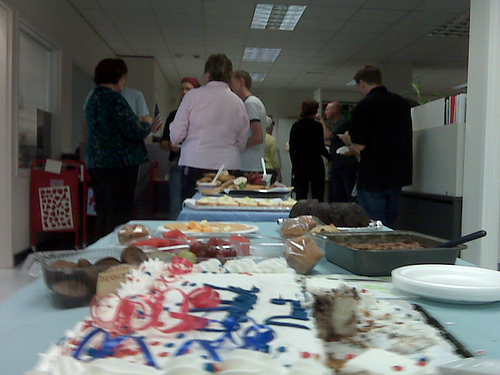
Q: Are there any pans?
A: Yes, there is a pan.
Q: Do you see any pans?
A: Yes, there is a pan.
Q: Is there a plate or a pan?
A: Yes, there is a pan.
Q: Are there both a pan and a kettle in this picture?
A: No, there is a pan but no kettles.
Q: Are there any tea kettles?
A: No, there are no tea kettles.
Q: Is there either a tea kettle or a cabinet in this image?
A: No, there are no tea kettles or cabinets.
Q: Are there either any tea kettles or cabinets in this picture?
A: No, there are no tea kettles or cabinets.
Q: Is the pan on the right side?
A: Yes, the pan is on the right of the image.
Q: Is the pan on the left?
A: No, the pan is on the right of the image.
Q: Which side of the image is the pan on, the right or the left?
A: The pan is on the right of the image.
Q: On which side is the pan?
A: The pan is on the right of the image.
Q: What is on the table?
A: The pan is on the table.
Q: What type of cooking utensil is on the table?
A: The cooking utensil is a pan.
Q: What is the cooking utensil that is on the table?
A: The cooking utensil is a pan.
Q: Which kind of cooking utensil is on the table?
A: The cooking utensil is a pan.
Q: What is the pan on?
A: The pan is on the table.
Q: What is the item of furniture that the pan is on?
A: The piece of furniture is a table.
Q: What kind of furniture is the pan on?
A: The pan is on the table.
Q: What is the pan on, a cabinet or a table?
A: The pan is on a table.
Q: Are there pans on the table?
A: Yes, there is a pan on the table.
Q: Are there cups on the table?
A: No, there is a pan on the table.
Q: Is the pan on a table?
A: Yes, the pan is on a table.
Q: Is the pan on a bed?
A: No, the pan is on a table.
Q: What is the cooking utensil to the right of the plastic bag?
A: The cooking utensil is a pan.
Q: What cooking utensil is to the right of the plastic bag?
A: The cooking utensil is a pan.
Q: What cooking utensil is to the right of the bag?
A: The cooking utensil is a pan.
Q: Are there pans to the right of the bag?
A: Yes, there is a pan to the right of the bag.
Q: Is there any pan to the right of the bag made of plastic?
A: Yes, there is a pan to the right of the bag.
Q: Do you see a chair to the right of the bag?
A: No, there is a pan to the right of the bag.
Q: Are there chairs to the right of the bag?
A: No, there is a pan to the right of the bag.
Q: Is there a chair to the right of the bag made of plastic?
A: No, there is a pan to the right of the bag.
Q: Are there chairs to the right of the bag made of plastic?
A: No, there is a pan to the right of the bag.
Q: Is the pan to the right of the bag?
A: Yes, the pan is to the right of the bag.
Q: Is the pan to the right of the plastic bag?
A: Yes, the pan is to the right of the bag.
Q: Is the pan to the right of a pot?
A: No, the pan is to the right of the bag.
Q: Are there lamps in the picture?
A: No, there are no lamps.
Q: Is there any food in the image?
A: Yes, there is food.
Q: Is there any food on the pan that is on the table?
A: Yes, there is food on the pan.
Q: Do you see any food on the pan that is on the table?
A: Yes, there is food on the pan.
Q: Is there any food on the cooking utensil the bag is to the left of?
A: Yes, there is food on the pan.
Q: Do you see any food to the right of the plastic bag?
A: Yes, there is food to the right of the bag.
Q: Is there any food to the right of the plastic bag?
A: Yes, there is food to the right of the bag.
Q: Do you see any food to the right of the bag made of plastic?
A: Yes, there is food to the right of the bag.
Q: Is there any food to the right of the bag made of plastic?
A: Yes, there is food to the right of the bag.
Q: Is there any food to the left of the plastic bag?
A: No, the food is to the right of the bag.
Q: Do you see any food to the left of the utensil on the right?
A: Yes, there is food to the left of the utensil.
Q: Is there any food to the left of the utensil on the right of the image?
A: Yes, there is food to the left of the utensil.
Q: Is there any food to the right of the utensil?
A: No, the food is to the left of the utensil.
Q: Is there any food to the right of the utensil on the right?
A: No, the food is to the left of the utensil.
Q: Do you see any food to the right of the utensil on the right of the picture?
A: No, the food is to the left of the utensil.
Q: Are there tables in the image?
A: Yes, there is a table.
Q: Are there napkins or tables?
A: Yes, there is a table.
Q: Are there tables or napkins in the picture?
A: Yes, there is a table.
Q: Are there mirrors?
A: No, there are no mirrors.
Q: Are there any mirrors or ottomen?
A: No, there are no mirrors or ottomen.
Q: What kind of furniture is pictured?
A: The furniture is a table.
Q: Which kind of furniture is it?
A: The piece of furniture is a table.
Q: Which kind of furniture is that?
A: This is a table.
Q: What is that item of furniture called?
A: This is a table.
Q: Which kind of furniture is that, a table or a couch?
A: This is a table.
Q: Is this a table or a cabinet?
A: This is a table.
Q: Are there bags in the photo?
A: Yes, there is a bag.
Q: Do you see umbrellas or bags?
A: Yes, there is a bag.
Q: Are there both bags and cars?
A: No, there is a bag but no cars.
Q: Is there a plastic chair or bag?
A: Yes, there is a plastic bag.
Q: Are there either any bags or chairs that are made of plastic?
A: Yes, the bag is made of plastic.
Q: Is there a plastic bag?
A: Yes, there is a bag that is made of plastic.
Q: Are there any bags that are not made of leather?
A: Yes, there is a bag that is made of plastic.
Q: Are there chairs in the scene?
A: No, there are no chairs.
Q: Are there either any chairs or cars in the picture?
A: No, there are no chairs or cars.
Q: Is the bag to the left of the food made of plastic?
A: Yes, the bag is made of plastic.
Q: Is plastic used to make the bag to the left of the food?
A: Yes, the bag is made of plastic.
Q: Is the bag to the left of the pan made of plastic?
A: Yes, the bag is made of plastic.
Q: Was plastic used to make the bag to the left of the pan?
A: Yes, the bag is made of plastic.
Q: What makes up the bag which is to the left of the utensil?
A: The bag is made of plastic.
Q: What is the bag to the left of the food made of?
A: The bag is made of plastic.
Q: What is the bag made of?
A: The bag is made of plastic.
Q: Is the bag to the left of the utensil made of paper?
A: No, the bag is made of plastic.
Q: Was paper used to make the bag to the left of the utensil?
A: No, the bag is made of plastic.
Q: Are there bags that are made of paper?
A: No, there is a bag but it is made of plastic.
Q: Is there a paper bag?
A: No, there is a bag but it is made of plastic.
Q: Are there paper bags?
A: No, there is a bag but it is made of plastic.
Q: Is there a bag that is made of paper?
A: No, there is a bag but it is made of plastic.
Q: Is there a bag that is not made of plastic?
A: No, there is a bag but it is made of plastic.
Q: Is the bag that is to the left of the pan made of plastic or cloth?
A: The bag is made of plastic.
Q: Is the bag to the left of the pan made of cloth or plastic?
A: The bag is made of plastic.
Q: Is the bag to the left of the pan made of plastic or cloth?
A: The bag is made of plastic.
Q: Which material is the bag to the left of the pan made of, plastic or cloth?
A: The bag is made of plastic.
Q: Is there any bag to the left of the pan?
A: Yes, there is a bag to the left of the pan.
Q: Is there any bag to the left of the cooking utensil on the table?
A: Yes, there is a bag to the left of the pan.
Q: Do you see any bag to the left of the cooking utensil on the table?
A: Yes, there is a bag to the left of the pan.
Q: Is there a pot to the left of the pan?
A: No, there is a bag to the left of the pan.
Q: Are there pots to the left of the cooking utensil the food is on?
A: No, there is a bag to the left of the pan.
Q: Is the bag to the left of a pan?
A: Yes, the bag is to the left of a pan.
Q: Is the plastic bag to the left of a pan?
A: Yes, the bag is to the left of a pan.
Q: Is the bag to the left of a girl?
A: No, the bag is to the left of a pan.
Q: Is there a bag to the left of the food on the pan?
A: Yes, there is a bag to the left of the food.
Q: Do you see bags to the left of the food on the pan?
A: Yes, there is a bag to the left of the food.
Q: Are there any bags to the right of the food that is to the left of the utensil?
A: No, the bag is to the left of the food.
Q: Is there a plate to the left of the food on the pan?
A: No, there is a bag to the left of the food.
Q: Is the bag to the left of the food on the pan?
A: Yes, the bag is to the left of the food.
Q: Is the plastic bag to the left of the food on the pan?
A: Yes, the bag is to the left of the food.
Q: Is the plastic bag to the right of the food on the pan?
A: No, the bag is to the left of the food.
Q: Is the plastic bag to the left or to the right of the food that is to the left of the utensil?
A: The bag is to the left of the food.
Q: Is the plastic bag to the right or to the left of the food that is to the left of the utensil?
A: The bag is to the left of the food.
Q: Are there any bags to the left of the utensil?
A: Yes, there is a bag to the left of the utensil.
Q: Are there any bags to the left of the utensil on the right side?
A: Yes, there is a bag to the left of the utensil.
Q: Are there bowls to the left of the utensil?
A: No, there is a bag to the left of the utensil.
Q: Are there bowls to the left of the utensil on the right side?
A: No, there is a bag to the left of the utensil.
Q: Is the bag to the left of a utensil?
A: Yes, the bag is to the left of a utensil.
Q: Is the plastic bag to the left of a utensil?
A: Yes, the bag is to the left of a utensil.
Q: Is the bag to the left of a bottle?
A: No, the bag is to the left of a utensil.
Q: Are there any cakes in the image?
A: Yes, there is a cake.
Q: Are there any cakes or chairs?
A: Yes, there is a cake.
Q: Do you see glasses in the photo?
A: No, there are no glasses.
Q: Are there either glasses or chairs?
A: No, there are no glasses or chairs.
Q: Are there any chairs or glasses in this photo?
A: No, there are no glasses or chairs.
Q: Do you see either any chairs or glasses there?
A: No, there are no glasses or chairs.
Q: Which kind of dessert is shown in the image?
A: The dessert is a cake.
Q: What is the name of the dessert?
A: The dessert is a cake.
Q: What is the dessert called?
A: The dessert is a cake.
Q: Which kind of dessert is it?
A: The dessert is a cake.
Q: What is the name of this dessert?
A: This is a cake.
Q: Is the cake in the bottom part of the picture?
A: Yes, the cake is in the bottom of the image.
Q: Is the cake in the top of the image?
A: No, the cake is in the bottom of the image.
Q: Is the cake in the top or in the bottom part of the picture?
A: The cake is in the bottom of the image.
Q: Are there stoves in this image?
A: No, there are no stoves.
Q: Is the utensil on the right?
A: Yes, the utensil is on the right of the image.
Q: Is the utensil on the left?
A: No, the utensil is on the right of the image.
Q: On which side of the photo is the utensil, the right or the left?
A: The utensil is on the right of the image.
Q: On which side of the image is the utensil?
A: The utensil is on the right of the image.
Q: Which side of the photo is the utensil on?
A: The utensil is on the right of the image.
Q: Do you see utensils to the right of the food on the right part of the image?
A: Yes, there is a utensil to the right of the food.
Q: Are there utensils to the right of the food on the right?
A: Yes, there is a utensil to the right of the food.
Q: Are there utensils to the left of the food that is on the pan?
A: No, the utensil is to the right of the food.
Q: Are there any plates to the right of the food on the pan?
A: No, there is a utensil to the right of the food.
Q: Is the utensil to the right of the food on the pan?
A: Yes, the utensil is to the right of the food.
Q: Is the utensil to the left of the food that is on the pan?
A: No, the utensil is to the right of the food.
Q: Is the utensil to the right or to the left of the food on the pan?
A: The utensil is to the right of the food.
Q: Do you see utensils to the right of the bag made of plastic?
A: Yes, there is a utensil to the right of the bag.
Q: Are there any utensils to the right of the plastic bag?
A: Yes, there is a utensil to the right of the bag.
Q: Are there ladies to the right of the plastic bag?
A: No, there is a utensil to the right of the bag.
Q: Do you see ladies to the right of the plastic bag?
A: No, there is a utensil to the right of the bag.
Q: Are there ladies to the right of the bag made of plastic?
A: No, there is a utensil to the right of the bag.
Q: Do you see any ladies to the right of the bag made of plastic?
A: No, there is a utensil to the right of the bag.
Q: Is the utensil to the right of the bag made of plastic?
A: Yes, the utensil is to the right of the bag.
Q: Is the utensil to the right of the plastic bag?
A: Yes, the utensil is to the right of the bag.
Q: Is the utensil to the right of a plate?
A: No, the utensil is to the right of the bag.